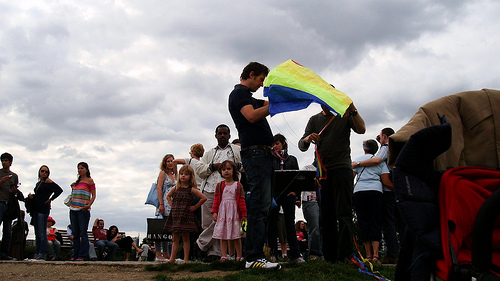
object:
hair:
[240, 60, 269, 79]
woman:
[155, 153, 182, 261]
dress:
[158, 170, 181, 217]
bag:
[144, 173, 174, 217]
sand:
[0, 257, 266, 278]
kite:
[260, 50, 353, 136]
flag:
[261, 59, 355, 117]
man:
[226, 61, 309, 274]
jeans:
[30, 207, 50, 259]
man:
[350, 127, 403, 265]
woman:
[351, 139, 391, 262]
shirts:
[353, 143, 389, 193]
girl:
[159, 166, 207, 265]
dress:
[162, 184, 201, 234]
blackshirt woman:
[29, 163, 62, 261]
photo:
[13, 11, 498, 279]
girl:
[210, 160, 247, 262]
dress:
[212, 180, 243, 240]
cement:
[120, 263, 145, 268]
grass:
[309, 257, 339, 271]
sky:
[0, 1, 497, 245]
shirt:
[226, 83, 274, 141]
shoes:
[223, 248, 288, 273]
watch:
[356, 161, 362, 167]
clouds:
[285, 0, 466, 63]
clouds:
[50, 31, 162, 108]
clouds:
[1, 111, 138, 156]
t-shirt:
[32, 181, 63, 214]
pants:
[34, 213, 49, 257]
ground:
[39, 261, 114, 279]